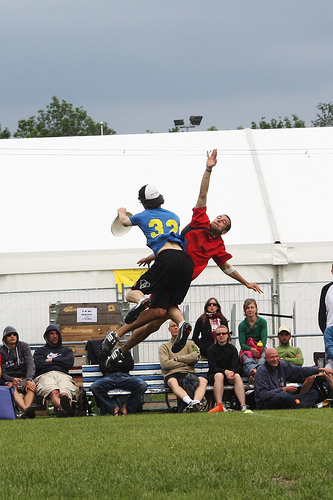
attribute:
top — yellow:
[254, 339, 263, 345]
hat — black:
[138, 184, 163, 209]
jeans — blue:
[91, 372, 145, 415]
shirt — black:
[33, 343, 74, 374]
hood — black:
[45, 325, 64, 345]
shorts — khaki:
[38, 374, 74, 404]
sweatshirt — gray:
[0, 327, 35, 378]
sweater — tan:
[158, 338, 199, 374]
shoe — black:
[102, 328, 118, 358]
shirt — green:
[238, 317, 268, 353]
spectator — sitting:
[209, 326, 251, 413]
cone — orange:
[207, 402, 224, 412]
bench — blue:
[80, 358, 262, 417]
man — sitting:
[254, 349, 330, 413]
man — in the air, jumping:
[118, 184, 191, 353]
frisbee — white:
[111, 210, 133, 238]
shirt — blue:
[131, 209, 185, 249]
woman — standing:
[192, 296, 229, 357]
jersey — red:
[179, 208, 232, 284]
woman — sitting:
[208, 327, 251, 412]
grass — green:
[7, 418, 54, 498]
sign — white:
[77, 307, 98, 322]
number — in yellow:
[148, 217, 180, 239]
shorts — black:
[131, 250, 194, 309]